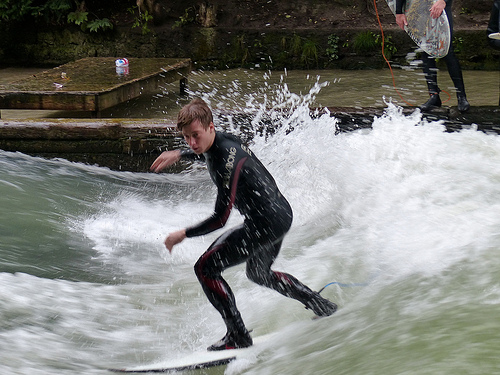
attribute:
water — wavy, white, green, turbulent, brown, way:
[4, 127, 500, 374]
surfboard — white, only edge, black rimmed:
[113, 264, 402, 372]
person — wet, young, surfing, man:
[157, 101, 345, 347]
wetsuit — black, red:
[173, 135, 342, 351]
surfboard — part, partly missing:
[389, 2, 453, 61]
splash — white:
[180, 73, 452, 160]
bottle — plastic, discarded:
[113, 54, 133, 72]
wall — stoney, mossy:
[3, 2, 500, 56]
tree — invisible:
[13, 6, 38, 23]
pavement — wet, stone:
[1, 67, 500, 134]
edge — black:
[112, 357, 231, 374]